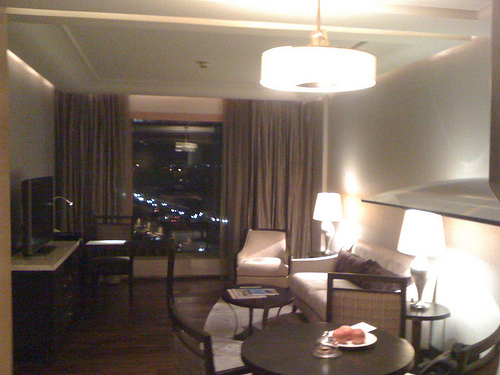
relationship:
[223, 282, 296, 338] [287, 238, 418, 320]
table in front of couch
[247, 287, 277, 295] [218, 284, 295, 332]
books on table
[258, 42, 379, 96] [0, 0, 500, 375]
chandelier in a hotel room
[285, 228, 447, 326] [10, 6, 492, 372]
couch in hotel room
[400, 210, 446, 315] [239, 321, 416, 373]
lamp on a table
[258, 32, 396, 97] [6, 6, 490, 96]
chandelier on a ceiling